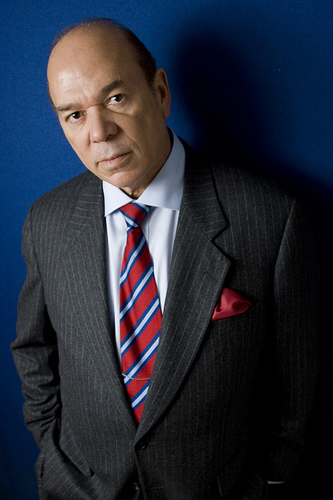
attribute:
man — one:
[41, 16, 168, 192]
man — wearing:
[17, 11, 262, 486]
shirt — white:
[101, 189, 171, 297]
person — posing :
[0, 32, 322, 495]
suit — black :
[7, 195, 319, 498]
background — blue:
[175, 11, 322, 162]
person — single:
[10, 19, 297, 491]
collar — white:
[102, 174, 180, 215]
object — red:
[213, 291, 254, 321]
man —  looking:
[12, 14, 322, 494]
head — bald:
[41, 21, 159, 74]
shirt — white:
[102, 181, 183, 293]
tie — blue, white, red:
[121, 209, 165, 385]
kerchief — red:
[214, 286, 247, 321]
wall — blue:
[169, 6, 320, 156]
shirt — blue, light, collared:
[107, 195, 169, 312]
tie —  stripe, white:
[119, 212, 165, 348]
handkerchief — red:
[213, 289, 251, 321]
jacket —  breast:
[27, 173, 321, 487]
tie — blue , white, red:
[121, 201, 166, 395]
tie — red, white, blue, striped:
[114, 202, 162, 421]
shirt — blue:
[101, 122, 185, 360]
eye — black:
[105, 93, 123, 105]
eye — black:
[64, 109, 83, 119]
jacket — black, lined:
[8, 128, 331, 497]